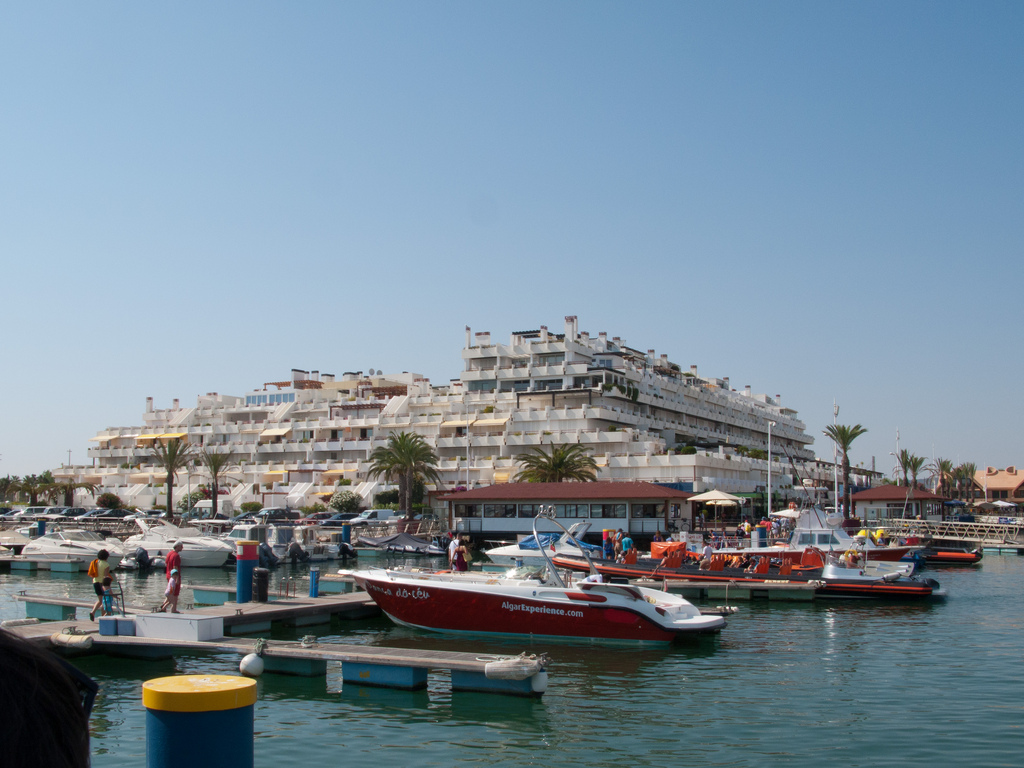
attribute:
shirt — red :
[159, 546, 182, 579]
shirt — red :
[163, 550, 182, 580]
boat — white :
[122, 515, 233, 572]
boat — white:
[23, 531, 119, 564]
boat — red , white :
[337, 502, 726, 648]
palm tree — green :
[506, 435, 601, 487]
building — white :
[51, 315, 883, 547]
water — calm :
[0, 546, 1022, 763]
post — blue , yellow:
[137, 665, 264, 765]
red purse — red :
[81, 548, 107, 581]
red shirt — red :
[152, 538, 191, 578]